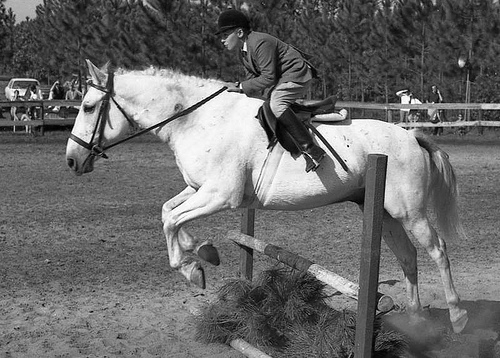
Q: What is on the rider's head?
A: A hat.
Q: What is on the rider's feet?
A: Boots.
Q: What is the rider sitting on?
A: A saddle.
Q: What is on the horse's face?
A: A harness.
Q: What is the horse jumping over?
A: A pole.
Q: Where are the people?
A: Outside of the wooden fence.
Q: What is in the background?
A: Trees.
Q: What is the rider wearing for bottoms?
A: Pants.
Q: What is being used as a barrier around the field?
A: A wooden fence.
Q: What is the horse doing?
A: Jumping.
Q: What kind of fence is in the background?
A: Wooden.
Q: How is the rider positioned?
A: Crouched.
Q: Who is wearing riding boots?
A: The rider.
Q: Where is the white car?
A: In the far background.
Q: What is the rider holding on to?
A: Reins.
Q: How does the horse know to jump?
A: He has been trained.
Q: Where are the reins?
A: In the rider's hands.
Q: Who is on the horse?
A: Woman with black helmet.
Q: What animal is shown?
A: Horse.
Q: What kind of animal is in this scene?
A: Horse.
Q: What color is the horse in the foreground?
A: White.